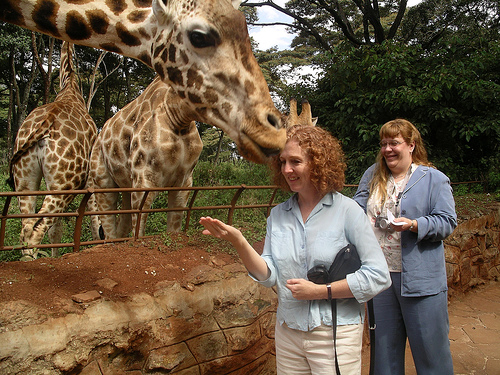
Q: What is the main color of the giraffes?
A: Brown and white.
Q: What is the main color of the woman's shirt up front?
A: Blue.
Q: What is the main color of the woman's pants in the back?
A: Blue.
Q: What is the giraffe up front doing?
A: Kissing the woman's hair.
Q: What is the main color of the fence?
A: Brown.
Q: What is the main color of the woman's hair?
A: Red.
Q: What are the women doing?
A: Feeding the giraffe.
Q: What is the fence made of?
A: Metal.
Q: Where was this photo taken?
A: At a zoo.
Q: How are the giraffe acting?
A: Friendly.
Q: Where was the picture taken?
A: Zoo.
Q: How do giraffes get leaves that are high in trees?
A: Long necks.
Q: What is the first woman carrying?
A: Purse.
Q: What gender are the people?
A: Female.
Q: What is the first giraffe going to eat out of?
A: Woman's hand.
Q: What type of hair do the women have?
A: Red hair.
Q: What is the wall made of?
A: Dirt.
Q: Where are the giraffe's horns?
A: On top of the head.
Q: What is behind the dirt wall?
A: A fence.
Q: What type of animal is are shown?
A: Giraffes.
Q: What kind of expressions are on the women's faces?
A: Smiles.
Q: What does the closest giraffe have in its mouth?
A: Hair.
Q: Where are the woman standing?
A: On stone.